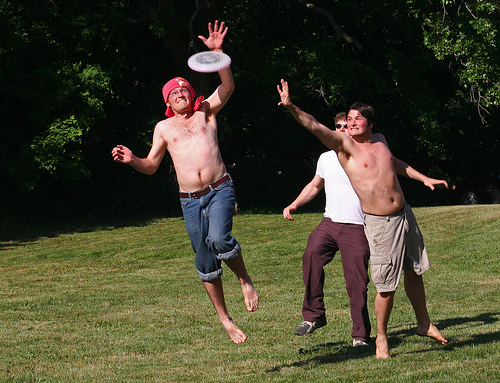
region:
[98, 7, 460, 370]
a group of three guys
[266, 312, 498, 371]
shadows on the grass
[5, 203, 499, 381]
green grass on the ground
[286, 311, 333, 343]
foot is in the air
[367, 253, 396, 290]
pocket on the side of the shorts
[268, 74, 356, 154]
arm is in the air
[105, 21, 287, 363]
man jumping in the air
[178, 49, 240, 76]
white frisbee in the air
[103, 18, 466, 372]
three guys playing frisbee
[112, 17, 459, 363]
three men playing frisbee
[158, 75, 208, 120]
a red shirt on a man's head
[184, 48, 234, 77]
a white frisbee in the air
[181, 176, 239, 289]
blue jeans rolled up on a man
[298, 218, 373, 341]
maroon pants on a man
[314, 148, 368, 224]
a white shirt on a man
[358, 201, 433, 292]
tan shorts on a man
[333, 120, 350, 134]
sunglasses on a man's face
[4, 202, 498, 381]
a grassy field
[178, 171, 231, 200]
a brown belt in a man's pants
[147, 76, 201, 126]
head of a person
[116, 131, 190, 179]
arm of a person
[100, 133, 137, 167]
hand of a person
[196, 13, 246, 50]
hand of a person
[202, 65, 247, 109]
arm of a person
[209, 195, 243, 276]
leg of a person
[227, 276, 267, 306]
feet of a person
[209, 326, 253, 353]
feet of a person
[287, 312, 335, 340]
leg of a person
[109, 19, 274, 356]
A man jumping up for a frisbee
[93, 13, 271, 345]
A man with a red shirt wrapped around his head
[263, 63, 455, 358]
A man reaching towards a frisbee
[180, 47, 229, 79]
A white round frisbee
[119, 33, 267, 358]
A man with his blue jeans rolled up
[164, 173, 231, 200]
A brown belt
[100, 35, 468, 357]
Three people playing with a frisbee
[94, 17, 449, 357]
Two men not wearing shirts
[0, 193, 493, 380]
A grassy field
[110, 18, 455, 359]
three men playing frisbee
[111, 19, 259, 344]
man jumping off the ground to catch a frisbee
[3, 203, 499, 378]
ground is covered in green grass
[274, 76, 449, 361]
man without a shirt is reaching out to catch a frisbee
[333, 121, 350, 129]
dark sunglasses on man's eyes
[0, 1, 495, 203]
trees in background behind the field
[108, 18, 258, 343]
man playing frisbee has bare feet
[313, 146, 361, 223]
white t-shirt on a man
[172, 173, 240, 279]
blue jeans are folded on the bottom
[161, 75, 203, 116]
red scarf on man's head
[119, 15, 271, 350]
man jumping to catch a frisbee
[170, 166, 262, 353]
denim blue jeans rolled up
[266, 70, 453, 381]
other men reaching for frisbee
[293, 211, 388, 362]
maroon colored long pants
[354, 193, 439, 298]
kahki cargo shorts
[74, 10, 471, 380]
men catching a frisbee in a field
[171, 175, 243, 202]
a brown leather belt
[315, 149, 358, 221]
a man wearing a white shirt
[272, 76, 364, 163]
a man with his arm stretched out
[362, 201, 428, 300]
a man wearing tan shorts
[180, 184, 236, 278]
a man wearing blue jeans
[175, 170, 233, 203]
a man wearing a brown belt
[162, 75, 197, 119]
a man wearing a red shirt on his head